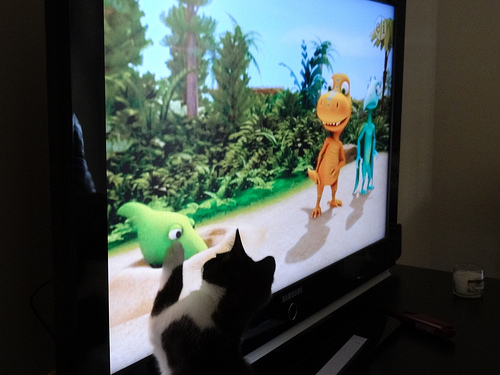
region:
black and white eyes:
[149, 215, 231, 248]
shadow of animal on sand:
[263, 216, 342, 264]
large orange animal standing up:
[283, 60, 353, 230]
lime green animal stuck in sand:
[120, 204, 207, 268]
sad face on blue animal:
[348, 65, 393, 192]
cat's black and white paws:
[143, 245, 202, 315]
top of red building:
[247, 70, 295, 93]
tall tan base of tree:
[141, 24, 226, 158]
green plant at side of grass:
[168, 165, 274, 214]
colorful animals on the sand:
[120, 62, 378, 252]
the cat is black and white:
[164, 251, 276, 373]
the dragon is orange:
[312, 85, 357, 230]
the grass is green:
[162, 120, 288, 193]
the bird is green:
[356, 77, 385, 186]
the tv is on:
[103, 70, 402, 318]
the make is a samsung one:
[282, 277, 327, 321]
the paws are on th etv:
[155, 241, 301, 371]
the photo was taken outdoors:
[50, 84, 497, 363]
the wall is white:
[435, 128, 494, 213]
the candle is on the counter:
[442, 263, 495, 309]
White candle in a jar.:
[453, 235, 493, 312]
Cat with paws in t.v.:
[141, 230, 283, 373]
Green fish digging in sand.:
[122, 162, 200, 284]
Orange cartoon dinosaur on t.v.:
[298, 57, 353, 232]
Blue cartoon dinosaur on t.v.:
[360, 65, 390, 202]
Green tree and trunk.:
[124, 33, 321, 191]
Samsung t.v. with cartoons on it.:
[266, 260, 335, 321]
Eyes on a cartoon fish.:
[150, 205, 213, 252]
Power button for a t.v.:
[260, 286, 304, 331]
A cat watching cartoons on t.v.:
[82, 63, 402, 373]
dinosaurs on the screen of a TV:
[287, 54, 388, 221]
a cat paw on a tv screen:
[157, 239, 187, 267]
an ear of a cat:
[224, 228, 252, 256]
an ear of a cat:
[257, 251, 279, 281]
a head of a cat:
[200, 227, 295, 304]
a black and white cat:
[165, 242, 281, 367]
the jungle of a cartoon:
[176, 37, 262, 173]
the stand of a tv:
[323, 321, 387, 370]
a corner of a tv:
[369, 214, 416, 274]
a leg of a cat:
[144, 242, 188, 342]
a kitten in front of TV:
[121, 194, 298, 373]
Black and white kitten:
[136, 216, 257, 371]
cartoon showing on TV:
[150, 12, 465, 252]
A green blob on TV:
[100, 36, 307, 332]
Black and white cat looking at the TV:
[86, 141, 322, 372]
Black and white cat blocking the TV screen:
[125, 167, 335, 372]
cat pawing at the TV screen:
[130, 99, 346, 374]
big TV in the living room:
[118, 59, 499, 371]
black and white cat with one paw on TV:
[66, 44, 369, 373]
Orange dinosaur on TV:
[253, 24, 481, 318]